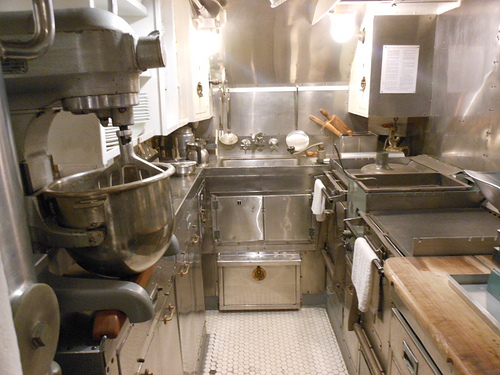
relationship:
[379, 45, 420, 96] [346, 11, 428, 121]
paper affixed to cabinet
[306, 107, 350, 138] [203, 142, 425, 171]
knife on counter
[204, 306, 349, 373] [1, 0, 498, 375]
floor in kitchen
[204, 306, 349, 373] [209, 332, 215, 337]
floor has tile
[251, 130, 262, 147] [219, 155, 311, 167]
faucet in sink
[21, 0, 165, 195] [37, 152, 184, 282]
mixer in bowl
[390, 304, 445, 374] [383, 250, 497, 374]
drawer under counter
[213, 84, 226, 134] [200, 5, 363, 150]
utensils on wall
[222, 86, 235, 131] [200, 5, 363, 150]
utensils on wall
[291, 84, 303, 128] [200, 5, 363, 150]
utensils on wall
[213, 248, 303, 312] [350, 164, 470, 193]
box in front of sink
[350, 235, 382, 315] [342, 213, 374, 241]
towel on oven handle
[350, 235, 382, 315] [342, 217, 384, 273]
towel on handle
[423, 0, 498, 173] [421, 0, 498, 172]
metal back on wall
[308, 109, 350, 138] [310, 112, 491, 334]
knife on counter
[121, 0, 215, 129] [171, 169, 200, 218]
cabinets above countertops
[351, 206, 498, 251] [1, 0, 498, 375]
grill in kitchen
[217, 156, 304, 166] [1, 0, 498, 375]
sink in kitchen